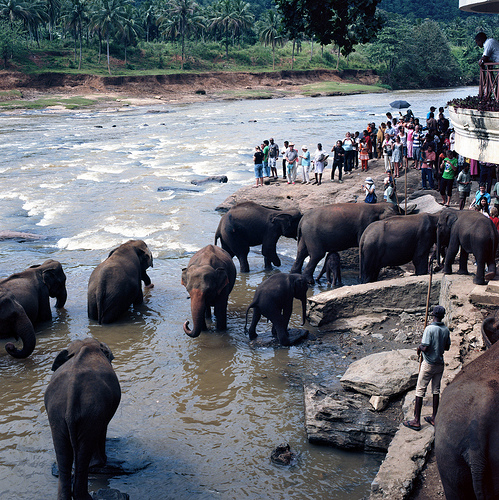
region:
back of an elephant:
[41, 339, 127, 491]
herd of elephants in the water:
[0, 193, 498, 495]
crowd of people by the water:
[247, 109, 498, 215]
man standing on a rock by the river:
[397, 294, 455, 435]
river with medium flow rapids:
[5, 84, 486, 498]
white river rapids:
[0, 124, 244, 267]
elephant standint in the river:
[183, 245, 235, 341]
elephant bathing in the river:
[84, 234, 156, 326]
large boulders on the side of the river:
[298, 270, 496, 495]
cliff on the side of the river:
[0, 67, 377, 109]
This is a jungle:
[41, 14, 421, 120]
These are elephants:
[17, 253, 215, 460]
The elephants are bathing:
[45, 259, 229, 448]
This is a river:
[37, 124, 230, 245]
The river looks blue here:
[59, 124, 254, 249]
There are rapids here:
[27, 138, 141, 239]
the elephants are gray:
[42, 318, 144, 479]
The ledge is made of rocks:
[325, 356, 421, 455]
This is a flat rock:
[342, 350, 447, 413]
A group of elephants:
[0, 198, 497, 498]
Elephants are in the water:
[2, 202, 314, 498]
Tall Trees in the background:
[1, 0, 368, 71]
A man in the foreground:
[395, 293, 454, 444]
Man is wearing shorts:
[405, 360, 447, 436]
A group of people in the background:
[235, 88, 496, 224]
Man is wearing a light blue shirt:
[412, 316, 452, 368]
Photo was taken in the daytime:
[3, 8, 496, 498]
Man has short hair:
[421, 294, 455, 328]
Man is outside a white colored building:
[437, 0, 498, 169]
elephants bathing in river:
[0, 198, 497, 493]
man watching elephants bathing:
[409, 269, 449, 432]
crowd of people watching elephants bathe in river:
[245, 104, 489, 202]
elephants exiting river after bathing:
[208, 196, 497, 276]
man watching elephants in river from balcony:
[464, 29, 498, 90]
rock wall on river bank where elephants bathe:
[301, 269, 496, 498]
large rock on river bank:
[339, 343, 427, 400]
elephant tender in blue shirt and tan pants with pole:
[412, 253, 451, 435]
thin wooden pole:
[422, 253, 436, 327]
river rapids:
[6, 115, 275, 253]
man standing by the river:
[407, 300, 453, 430]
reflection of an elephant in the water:
[176, 328, 250, 430]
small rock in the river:
[272, 438, 292, 467]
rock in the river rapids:
[193, 169, 229, 188]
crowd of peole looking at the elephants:
[256, 104, 496, 213]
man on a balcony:
[474, 29, 493, 66]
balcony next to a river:
[448, 2, 497, 154]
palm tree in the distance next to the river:
[258, 10, 287, 68]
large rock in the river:
[387, 97, 411, 109]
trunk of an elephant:
[182, 280, 211, 337]